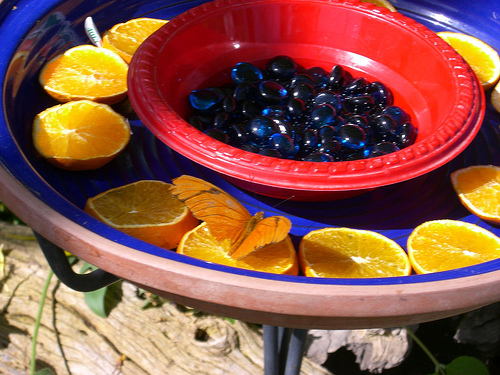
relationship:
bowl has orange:
[0, 1, 498, 329] [299, 222, 410, 281]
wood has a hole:
[0, 220, 327, 373] [194, 324, 211, 341]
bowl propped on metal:
[125, 0, 486, 201] [242, 310, 313, 372]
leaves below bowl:
[398, 326, 498, 373] [125, 0, 486, 201]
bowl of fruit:
[0, 1, 498, 329] [106, 170, 382, 288]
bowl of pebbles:
[0, 1, 498, 329] [164, 53, 384, 188]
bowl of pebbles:
[125, 0, 486, 201] [234, 67, 381, 143]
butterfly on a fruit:
[165, 174, 293, 259] [85, 177, 195, 247]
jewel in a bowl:
[370, 81, 388, 106] [125, 0, 486, 201]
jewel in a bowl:
[307, 102, 335, 127] [125, 0, 486, 201]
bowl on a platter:
[125, 0, 486, 201] [1, 3, 498, 323]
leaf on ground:
[76, 262, 116, 318] [0, 197, 499, 372]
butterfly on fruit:
[165, 174, 293, 259] [34, 100, 133, 166]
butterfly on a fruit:
[173, 184, 287, 235] [300, 227, 410, 278]